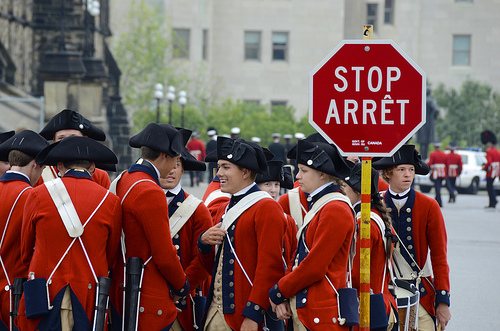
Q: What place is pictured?
A: It is a street.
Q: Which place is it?
A: It is a street.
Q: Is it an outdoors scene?
A: Yes, it is outdoors.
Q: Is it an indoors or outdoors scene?
A: It is outdoors.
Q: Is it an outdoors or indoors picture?
A: It is outdoors.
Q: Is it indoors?
A: No, it is outdoors.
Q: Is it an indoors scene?
A: No, it is outdoors.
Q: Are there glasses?
A: No, there are no glasses.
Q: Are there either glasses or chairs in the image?
A: No, there are no glasses or chairs.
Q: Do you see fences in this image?
A: No, there are no fences.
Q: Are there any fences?
A: No, there are no fences.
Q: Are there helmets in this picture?
A: No, there are no helmets.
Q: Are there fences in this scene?
A: No, there are no fences.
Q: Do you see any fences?
A: No, there are no fences.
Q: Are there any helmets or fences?
A: No, there are no fences or helmets.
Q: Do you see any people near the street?
A: Yes, there is a person near the street.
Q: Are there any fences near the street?
A: No, there is a person near the street.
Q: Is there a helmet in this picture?
A: No, there are no helmets.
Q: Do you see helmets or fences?
A: No, there are no helmets or fences.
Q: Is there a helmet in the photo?
A: No, there are no helmets.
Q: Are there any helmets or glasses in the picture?
A: No, there are no helmets or glasses.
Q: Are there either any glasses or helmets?
A: No, there are no helmets or glasses.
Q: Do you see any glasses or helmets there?
A: No, there are no helmets or glasses.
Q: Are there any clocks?
A: No, there are no clocks.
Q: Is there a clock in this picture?
A: No, there are no clocks.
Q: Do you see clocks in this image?
A: No, there are no clocks.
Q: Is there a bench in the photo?
A: No, there are no benches.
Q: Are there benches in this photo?
A: No, there are no benches.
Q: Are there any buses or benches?
A: No, there are no benches or buses.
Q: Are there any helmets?
A: No, there are no helmets.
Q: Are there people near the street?
A: Yes, there is a person near the street.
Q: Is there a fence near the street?
A: No, there is a person near the street.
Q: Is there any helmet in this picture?
A: No, there are no helmets.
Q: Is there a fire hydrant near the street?
A: No, there is a person near the street.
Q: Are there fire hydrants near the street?
A: No, there is a person near the street.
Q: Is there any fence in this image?
A: No, there are no fences.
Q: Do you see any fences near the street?
A: No, there is a person near the street.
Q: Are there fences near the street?
A: No, there is a person near the street.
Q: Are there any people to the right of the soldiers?
A: Yes, there is a person to the right of the soldiers.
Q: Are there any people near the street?
A: Yes, there is a person near the street.